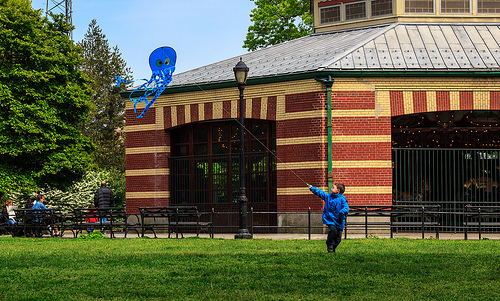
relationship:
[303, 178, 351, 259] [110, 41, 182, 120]
kid flying a kite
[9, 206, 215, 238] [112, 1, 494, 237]
benches facing building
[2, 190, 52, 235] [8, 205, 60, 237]
people sitting on bench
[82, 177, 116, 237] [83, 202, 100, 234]
adult walking with child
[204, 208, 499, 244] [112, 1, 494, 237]
fence in front building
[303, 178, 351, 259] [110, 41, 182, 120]
boy flying a kite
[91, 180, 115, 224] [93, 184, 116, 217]
adult in black jacket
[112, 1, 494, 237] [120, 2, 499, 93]
building has a roof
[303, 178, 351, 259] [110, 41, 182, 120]
boy flying kite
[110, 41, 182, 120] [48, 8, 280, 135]
kite in air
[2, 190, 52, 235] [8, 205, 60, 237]
people sitting on benches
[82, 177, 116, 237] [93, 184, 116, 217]
person with coat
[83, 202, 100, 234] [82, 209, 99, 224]
child with red coat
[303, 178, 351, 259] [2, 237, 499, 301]
boy running in yard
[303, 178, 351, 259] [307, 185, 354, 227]
boy wearing blue sweater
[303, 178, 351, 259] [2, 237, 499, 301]
boy in park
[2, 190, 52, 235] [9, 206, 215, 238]
people sitting on benches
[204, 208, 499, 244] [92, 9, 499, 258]
fence around pavillion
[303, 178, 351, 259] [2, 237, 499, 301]
boy running across grass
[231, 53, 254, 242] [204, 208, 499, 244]
post front of fence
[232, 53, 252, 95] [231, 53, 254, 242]
light top of lamp post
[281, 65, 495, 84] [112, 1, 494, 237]
gutter attached to house